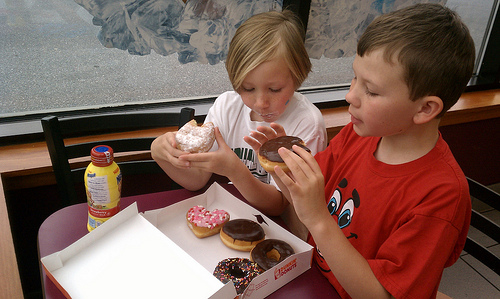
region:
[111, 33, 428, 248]
the kids are eating doughnuts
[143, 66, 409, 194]
the kids are eating doughnuts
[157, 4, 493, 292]
two kids eating donuts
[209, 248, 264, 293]
donut with colorful sprinkles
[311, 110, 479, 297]
red T-shirt with face on it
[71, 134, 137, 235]
Nesquik plastic bottle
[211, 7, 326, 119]
girl with blonde highlights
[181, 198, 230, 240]
heart shaped pink donut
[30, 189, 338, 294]
white donute box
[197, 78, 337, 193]
boy's white T-shirt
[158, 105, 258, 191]
hand holding white sugar donut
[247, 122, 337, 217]
hand holding chocolate glazed donut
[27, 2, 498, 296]
young boy and girl eating donuts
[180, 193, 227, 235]
pink heart donut with white red and pink sprinkles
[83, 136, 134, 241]
bottle of nesquick on table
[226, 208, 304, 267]
two chocolate covered donuts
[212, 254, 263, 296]
chocolate covered donut with rainbow sprinkles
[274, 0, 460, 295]
boy with orange smiley face shirt eating a donut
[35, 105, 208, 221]
black chair at table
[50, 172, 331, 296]
box of donuts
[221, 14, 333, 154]
young girl with powdered sugar on face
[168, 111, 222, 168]
powdered donut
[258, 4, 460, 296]
Boy is holding a donut.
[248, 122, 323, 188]
Donut has chocolate icing.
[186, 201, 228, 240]
A heart shaped donut.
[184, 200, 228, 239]
The donut has sprinkles.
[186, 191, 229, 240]
Red, white and pink sprinkles.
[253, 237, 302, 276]
The donut is round.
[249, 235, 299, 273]
Donut has a hole.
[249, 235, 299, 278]
Donut has chocolate icing.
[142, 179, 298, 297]
Donuts in a box.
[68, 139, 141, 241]
Bottle of chocolate milk.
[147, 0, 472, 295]
two boys eating donuts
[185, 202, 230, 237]
heart shaped doughnut with sprinkles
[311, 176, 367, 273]
smiley face on orange shirt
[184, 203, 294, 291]
four donuts in box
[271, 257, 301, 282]
Dunkin Donuts label on box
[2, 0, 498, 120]
windows with scenery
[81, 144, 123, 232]
bottle of nesquik milk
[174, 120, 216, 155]
white frosted jelly donut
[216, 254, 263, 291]
sprinkles on chocolate frosting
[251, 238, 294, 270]
chocolate frosted donut